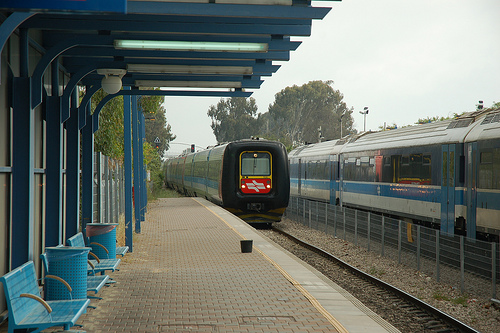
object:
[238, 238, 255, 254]
black object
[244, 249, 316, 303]
line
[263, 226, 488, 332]
tracks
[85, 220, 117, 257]
garbage can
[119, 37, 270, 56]
tube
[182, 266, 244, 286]
brick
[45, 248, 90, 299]
can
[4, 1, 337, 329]
building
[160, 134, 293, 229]
train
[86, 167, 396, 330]
ground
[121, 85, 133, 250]
pole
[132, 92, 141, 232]
pole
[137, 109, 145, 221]
pole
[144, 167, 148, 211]
pole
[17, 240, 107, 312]
handles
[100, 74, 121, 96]
globe light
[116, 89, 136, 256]
pole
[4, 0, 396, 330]
platform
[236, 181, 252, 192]
lights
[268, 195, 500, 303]
fence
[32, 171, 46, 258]
window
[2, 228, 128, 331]
bench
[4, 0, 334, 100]
overhang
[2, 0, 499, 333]
train station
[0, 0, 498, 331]
station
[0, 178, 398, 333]
sidewalk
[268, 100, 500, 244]
freight train